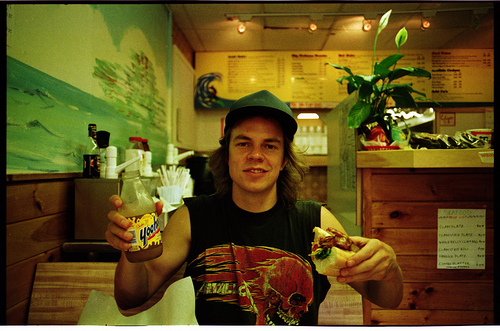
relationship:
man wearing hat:
[155, 90, 381, 324] [231, 91, 299, 128]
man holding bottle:
[155, 90, 381, 324] [119, 170, 163, 262]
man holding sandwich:
[155, 90, 381, 324] [309, 231, 362, 275]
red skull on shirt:
[258, 259, 306, 323] [181, 193, 325, 330]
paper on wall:
[441, 211, 481, 272] [368, 171, 491, 329]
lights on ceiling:
[230, 10, 434, 42] [172, 5, 498, 53]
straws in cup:
[159, 168, 190, 184] [160, 186, 184, 202]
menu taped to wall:
[441, 211, 481, 272] [368, 171, 491, 329]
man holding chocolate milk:
[155, 90, 381, 324] [119, 170, 163, 262]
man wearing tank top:
[155, 90, 381, 324] [181, 193, 325, 330]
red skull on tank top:
[258, 259, 306, 323] [181, 193, 325, 330]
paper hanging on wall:
[441, 211, 481, 272] [368, 171, 491, 329]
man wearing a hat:
[155, 90, 381, 324] [231, 91, 299, 128]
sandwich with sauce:
[309, 231, 362, 275] [323, 246, 351, 255]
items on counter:
[350, 114, 494, 155] [355, 148, 499, 168]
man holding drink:
[155, 90, 381, 324] [119, 170, 163, 262]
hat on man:
[231, 91, 299, 128] [155, 90, 381, 324]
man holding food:
[155, 90, 381, 324] [309, 231, 362, 275]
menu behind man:
[194, 50, 499, 101] [155, 90, 381, 324]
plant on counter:
[335, 20, 423, 143] [355, 148, 499, 168]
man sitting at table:
[104, 89, 403, 326] [377, 320, 378, 321]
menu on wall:
[194, 50, 499, 101] [180, 53, 487, 173]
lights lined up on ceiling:
[230, 10, 434, 42] [172, 5, 498, 53]